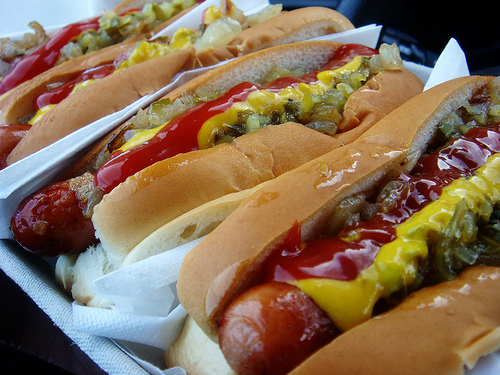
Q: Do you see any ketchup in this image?
A: Yes, there is ketchup.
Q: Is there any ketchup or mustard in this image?
A: Yes, there is ketchup.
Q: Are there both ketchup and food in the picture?
A: Yes, there are both ketchup and food.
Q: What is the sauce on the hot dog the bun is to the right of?
A: The sauce is ketchup.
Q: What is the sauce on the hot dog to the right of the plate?
A: The sauce is ketchup.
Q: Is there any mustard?
A: Yes, there is mustard.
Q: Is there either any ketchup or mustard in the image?
A: Yes, there is mustard.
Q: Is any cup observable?
A: No, there are no cups.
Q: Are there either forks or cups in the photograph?
A: No, there are no cups or forks.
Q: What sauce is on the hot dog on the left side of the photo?
A: The sauce is mustard.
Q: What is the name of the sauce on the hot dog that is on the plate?
A: The sauce is mustard.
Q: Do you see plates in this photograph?
A: Yes, there is a plate.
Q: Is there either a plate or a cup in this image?
A: Yes, there is a plate.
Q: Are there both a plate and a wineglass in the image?
A: No, there is a plate but no wine glasses.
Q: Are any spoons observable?
A: No, there are no spoons.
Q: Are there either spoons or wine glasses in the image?
A: No, there are no spoons or wine glasses.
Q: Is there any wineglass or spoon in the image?
A: No, there are no spoons or wine glasses.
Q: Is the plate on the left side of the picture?
A: Yes, the plate is on the left of the image.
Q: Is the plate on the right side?
A: No, the plate is on the left of the image.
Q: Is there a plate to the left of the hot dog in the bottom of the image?
A: Yes, there is a plate to the left of the hot dog.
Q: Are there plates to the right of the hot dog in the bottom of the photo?
A: No, the plate is to the left of the hot dog.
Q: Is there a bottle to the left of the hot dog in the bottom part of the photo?
A: No, there is a plate to the left of the hot dog.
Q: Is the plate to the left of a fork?
A: No, the plate is to the left of the hot dog.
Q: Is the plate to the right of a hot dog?
A: No, the plate is to the left of a hot dog.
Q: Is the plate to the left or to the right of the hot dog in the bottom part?
A: The plate is to the left of the hot dog.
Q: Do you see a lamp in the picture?
A: No, there are no lamps.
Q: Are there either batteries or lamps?
A: No, there are no lamps or batteries.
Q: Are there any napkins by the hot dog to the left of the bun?
A: Yes, there is a napkin by the hot dog.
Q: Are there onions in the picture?
A: Yes, there are onions.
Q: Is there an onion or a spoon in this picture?
A: Yes, there are onions.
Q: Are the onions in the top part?
A: Yes, the onions are in the top of the image.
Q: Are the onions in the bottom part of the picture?
A: No, the onions are in the top of the image.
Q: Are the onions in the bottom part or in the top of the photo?
A: The onions are in the top of the image.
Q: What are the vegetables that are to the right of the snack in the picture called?
A: The vegetables are onions.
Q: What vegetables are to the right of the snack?
A: The vegetables are onions.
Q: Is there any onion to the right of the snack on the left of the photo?
A: Yes, there are onions to the right of the snack.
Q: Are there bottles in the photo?
A: No, there are no bottles.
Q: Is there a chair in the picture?
A: No, there are no chairs.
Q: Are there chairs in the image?
A: No, there are no chairs.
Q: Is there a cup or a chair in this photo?
A: No, there are no chairs or cups.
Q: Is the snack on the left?
A: Yes, the snack is on the left of the image.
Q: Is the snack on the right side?
A: No, the snack is on the left of the image.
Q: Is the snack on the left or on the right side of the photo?
A: The snack is on the left of the image.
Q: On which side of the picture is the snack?
A: The snack is on the left of the image.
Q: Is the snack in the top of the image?
A: Yes, the snack is in the top of the image.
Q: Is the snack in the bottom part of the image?
A: No, the snack is in the top of the image.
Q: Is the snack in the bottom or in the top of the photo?
A: The snack is in the top of the image.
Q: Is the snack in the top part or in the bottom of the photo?
A: The snack is in the top of the image.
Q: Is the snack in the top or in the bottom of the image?
A: The snack is in the top of the image.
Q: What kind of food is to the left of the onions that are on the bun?
A: The food is a snack.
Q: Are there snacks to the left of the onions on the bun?
A: Yes, there is a snack to the left of the onions.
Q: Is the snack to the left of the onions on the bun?
A: Yes, the snack is to the left of the onions.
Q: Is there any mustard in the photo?
A: Yes, there is mustard.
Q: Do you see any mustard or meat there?
A: Yes, there is mustard.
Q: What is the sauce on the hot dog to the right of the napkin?
A: The sauce is mustard.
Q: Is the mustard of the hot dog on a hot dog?
A: Yes, the mustard is on a hot dog.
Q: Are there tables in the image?
A: Yes, there is a table.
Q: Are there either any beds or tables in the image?
A: Yes, there is a table.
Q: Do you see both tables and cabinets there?
A: No, there is a table but no cabinets.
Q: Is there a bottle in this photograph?
A: No, there are no bottles.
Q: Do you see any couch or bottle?
A: No, there are no bottles or couches.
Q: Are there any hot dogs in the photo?
A: Yes, there is a hot dog.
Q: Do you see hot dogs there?
A: Yes, there is a hot dog.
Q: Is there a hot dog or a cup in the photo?
A: Yes, there is a hot dog.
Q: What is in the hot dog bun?
A: The hot dog is in the bun.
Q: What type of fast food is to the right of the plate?
A: The food is a hot dog.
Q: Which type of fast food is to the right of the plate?
A: The food is a hot dog.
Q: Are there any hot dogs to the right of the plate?
A: Yes, there is a hot dog to the right of the plate.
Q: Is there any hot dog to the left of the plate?
A: No, the hot dog is to the right of the plate.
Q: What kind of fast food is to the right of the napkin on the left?
A: The food is a hot dog.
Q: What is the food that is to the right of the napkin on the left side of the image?
A: The food is a hot dog.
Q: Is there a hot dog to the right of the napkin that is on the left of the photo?
A: Yes, there is a hot dog to the right of the napkin.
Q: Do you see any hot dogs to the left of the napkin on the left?
A: No, the hot dog is to the right of the napkin.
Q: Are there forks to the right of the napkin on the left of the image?
A: No, there is a hot dog to the right of the napkin.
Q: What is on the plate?
A: The hot dog is on the plate.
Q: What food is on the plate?
A: The food is a hot dog.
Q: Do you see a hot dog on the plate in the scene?
A: Yes, there is a hot dog on the plate.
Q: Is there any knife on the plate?
A: No, there is a hot dog on the plate.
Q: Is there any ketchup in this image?
A: Yes, there is ketchup.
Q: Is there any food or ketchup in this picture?
A: Yes, there is ketchup.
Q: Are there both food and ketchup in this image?
A: Yes, there are both ketchup and food.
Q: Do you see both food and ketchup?
A: Yes, there are both ketchup and food.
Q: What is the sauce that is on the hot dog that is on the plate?
A: The sauce is ketchup.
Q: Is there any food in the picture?
A: Yes, there is food.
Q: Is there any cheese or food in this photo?
A: Yes, there is food.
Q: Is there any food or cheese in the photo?
A: Yes, there is food.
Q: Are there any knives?
A: No, there are no knives.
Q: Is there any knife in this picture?
A: No, there are no knives.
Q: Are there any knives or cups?
A: No, there are no knives or cups.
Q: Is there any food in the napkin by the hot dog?
A: Yes, there is food in the napkin.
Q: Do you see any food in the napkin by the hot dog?
A: Yes, there is food in the napkin.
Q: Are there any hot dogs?
A: Yes, there is a hot dog.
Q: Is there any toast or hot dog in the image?
A: Yes, there is a hot dog.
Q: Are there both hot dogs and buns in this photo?
A: Yes, there are both a hot dog and a bun.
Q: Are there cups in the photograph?
A: No, there are no cups.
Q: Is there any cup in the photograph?
A: No, there are no cups.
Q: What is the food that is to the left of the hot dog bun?
A: The food is a hot dog.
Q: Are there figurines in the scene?
A: No, there are no figurines.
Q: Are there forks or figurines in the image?
A: No, there are no figurines or forks.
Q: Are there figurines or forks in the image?
A: No, there are no figurines or forks.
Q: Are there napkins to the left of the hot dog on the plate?
A: Yes, there is a napkin to the left of the hot dog.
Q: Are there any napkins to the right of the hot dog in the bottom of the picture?
A: No, the napkin is to the left of the hot dog.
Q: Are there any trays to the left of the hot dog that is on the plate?
A: No, there is a napkin to the left of the hot dog.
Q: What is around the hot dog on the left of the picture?
A: The napkin is around the hot dog.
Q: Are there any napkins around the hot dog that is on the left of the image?
A: Yes, there is a napkin around the hot dog.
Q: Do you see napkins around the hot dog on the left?
A: Yes, there is a napkin around the hot dog.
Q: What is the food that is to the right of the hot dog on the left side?
A: The food is a bun.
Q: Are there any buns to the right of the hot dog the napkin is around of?
A: Yes, there is a bun to the right of the hot dog.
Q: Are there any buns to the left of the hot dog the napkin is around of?
A: No, the bun is to the right of the hot dog.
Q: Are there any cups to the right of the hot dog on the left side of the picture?
A: No, there is a bun to the right of the hot dog.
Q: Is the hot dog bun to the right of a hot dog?
A: Yes, the bun is to the right of a hot dog.